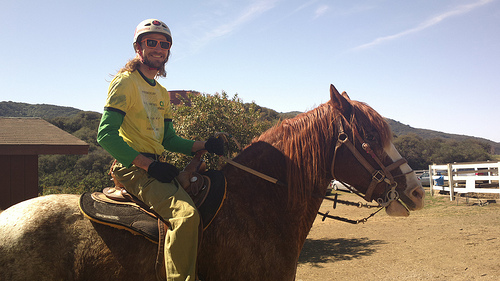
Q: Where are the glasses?
A: On face.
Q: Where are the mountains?
A: Background.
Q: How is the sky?
A: Clear.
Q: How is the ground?
A: Dry.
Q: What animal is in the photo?
A: A horse.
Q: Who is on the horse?
A: A man.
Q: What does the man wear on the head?
A: A helmet.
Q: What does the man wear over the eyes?
A: Sunglasses.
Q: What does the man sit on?
A: The saddle.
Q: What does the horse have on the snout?
A: The bridal.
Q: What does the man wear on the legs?
A: Pants.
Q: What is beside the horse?
A: A tree.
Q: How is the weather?
A: Sunny.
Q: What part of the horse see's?
A: Eyes.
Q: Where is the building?
A: Behind the man on a horse.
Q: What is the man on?
A: Saddle.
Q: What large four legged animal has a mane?
A: Horse.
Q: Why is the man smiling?
A: Happy.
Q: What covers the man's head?
A: Helmet.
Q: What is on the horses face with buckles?
A: Harnace.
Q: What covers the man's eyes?
A: Sunglasses.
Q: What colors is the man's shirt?
A: Yellow and Green.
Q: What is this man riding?
A: A horse.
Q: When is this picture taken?
A: Daytime.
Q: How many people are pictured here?
A: One.